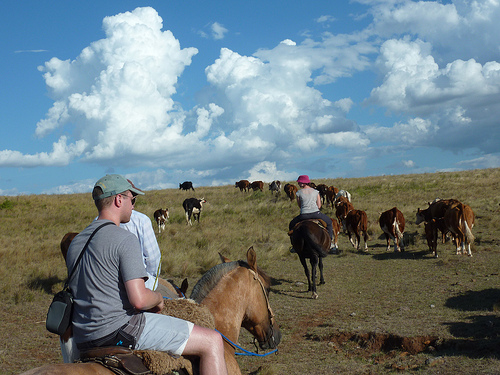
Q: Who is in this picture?
A: Three people.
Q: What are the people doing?
A: Riding horses.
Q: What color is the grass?
A: Green.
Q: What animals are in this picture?
A: Horses and cows.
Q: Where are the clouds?
A: In the sky.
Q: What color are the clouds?
A: White.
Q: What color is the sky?
A: Blue.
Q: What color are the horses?
A: Brown.